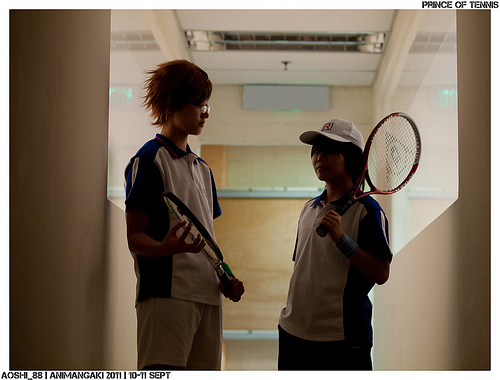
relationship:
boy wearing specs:
[123, 59, 245, 369] [192, 100, 212, 120]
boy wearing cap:
[276, 118, 393, 371] [298, 118, 365, 153]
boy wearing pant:
[276, 118, 393, 371] [273, 337, 379, 371]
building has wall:
[210, 41, 336, 186] [417, 212, 491, 304]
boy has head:
[123, 59, 245, 369] [150, 60, 208, 137]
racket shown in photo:
[346, 102, 441, 256] [11, 13, 484, 369]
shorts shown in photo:
[134, 297, 222, 370] [11, 13, 484, 369]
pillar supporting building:
[13, 11, 112, 368] [11, 11, 484, 366]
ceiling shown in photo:
[174, 30, 481, 147] [11, 13, 484, 369]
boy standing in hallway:
[276, 118, 393, 371] [106, 11, 485, 363]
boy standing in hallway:
[123, 59, 245, 369] [106, 11, 485, 363]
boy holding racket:
[121, 59, 248, 369] [155, 186, 260, 301]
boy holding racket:
[276, 115, 393, 375] [315, 111, 422, 238]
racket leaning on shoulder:
[315, 111, 422, 238] [345, 192, 385, 229]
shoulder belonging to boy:
[345, 192, 385, 229] [276, 115, 393, 375]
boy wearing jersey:
[121, 59, 248, 369] [121, 133, 223, 308]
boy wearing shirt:
[276, 118, 393, 371] [277, 188, 394, 343]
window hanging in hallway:
[383, 11, 459, 254] [106, 11, 485, 363]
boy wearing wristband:
[276, 115, 393, 375] [334, 232, 356, 259]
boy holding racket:
[276, 118, 393, 371] [315, 112, 421, 237]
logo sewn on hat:
[320, 120, 336, 131] [299, 118, 364, 155]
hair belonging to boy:
[142, 57, 212, 127] [123, 59, 245, 369]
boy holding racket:
[276, 118, 393, 371] [338, 109, 489, 214]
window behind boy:
[105, 4, 187, 226] [123, 59, 245, 369]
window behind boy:
[378, 11, 468, 269] [276, 118, 393, 371]